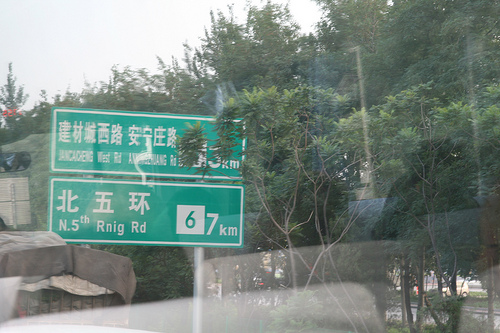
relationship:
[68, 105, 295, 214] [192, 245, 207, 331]
sign on a pole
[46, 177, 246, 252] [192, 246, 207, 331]
sign on a metal pole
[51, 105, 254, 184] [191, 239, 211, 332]
sign on pole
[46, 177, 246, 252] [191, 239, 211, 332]
sign on pole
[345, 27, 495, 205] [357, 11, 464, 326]
leaves on tree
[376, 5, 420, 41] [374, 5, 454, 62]
leaves in tree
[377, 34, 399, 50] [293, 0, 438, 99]
green leaves in tree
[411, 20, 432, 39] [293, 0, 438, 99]
green leaves in tree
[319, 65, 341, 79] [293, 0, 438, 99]
green leaves in tree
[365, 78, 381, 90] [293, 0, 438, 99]
green leaves in tree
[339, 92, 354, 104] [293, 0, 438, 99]
green leaves in tree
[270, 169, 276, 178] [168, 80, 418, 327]
leaf in tree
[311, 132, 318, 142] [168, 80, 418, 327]
leaf in tree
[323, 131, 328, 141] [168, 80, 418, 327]
leaf in tree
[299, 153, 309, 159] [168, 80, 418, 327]
leaf in tree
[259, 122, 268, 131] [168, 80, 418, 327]
leaf in tree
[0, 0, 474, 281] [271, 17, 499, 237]
leaves in tree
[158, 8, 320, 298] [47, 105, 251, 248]
trees behind highway sign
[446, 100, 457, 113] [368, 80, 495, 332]
leaf on tree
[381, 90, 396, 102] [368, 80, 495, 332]
leaf on tree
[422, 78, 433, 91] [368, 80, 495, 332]
leaf on tree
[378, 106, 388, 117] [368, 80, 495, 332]
leaf on tree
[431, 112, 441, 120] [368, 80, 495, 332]
leaf on tree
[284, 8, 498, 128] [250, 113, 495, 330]
leaves in tree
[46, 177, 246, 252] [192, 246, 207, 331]
sign in metal pole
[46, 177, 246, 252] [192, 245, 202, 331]
sign in pole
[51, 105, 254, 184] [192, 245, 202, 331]
sign in pole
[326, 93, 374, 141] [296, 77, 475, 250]
leaves are in tree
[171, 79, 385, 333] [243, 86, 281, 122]
trees are in leaves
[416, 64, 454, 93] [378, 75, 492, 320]
leaves are on tree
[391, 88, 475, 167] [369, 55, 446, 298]
leaves are on tree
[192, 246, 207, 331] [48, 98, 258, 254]
metal pole under sign